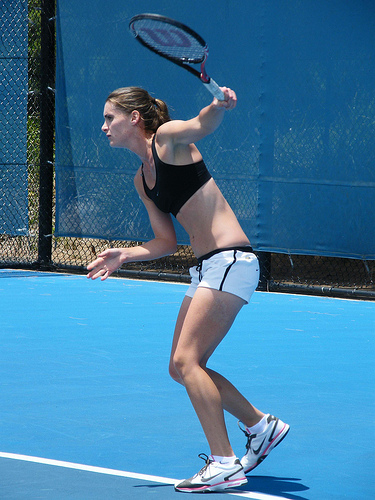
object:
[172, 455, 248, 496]
shoe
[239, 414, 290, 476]
shoe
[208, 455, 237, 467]
sock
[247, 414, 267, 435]
sock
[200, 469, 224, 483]
logo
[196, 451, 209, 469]
laces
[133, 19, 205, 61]
mesh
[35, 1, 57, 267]
fence post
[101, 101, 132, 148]
face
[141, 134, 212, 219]
bra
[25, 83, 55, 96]
hook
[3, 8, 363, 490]
tennis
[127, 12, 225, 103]
racket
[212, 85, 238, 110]
hand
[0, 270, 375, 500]
court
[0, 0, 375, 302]
fence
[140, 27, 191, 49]
w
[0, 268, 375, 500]
ground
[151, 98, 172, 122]
ponytail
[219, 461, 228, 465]
symbol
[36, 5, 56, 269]
pipe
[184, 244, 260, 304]
shorts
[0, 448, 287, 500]
boundary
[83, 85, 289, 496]
human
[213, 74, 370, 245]
tarp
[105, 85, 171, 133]
hair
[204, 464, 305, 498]
shadow